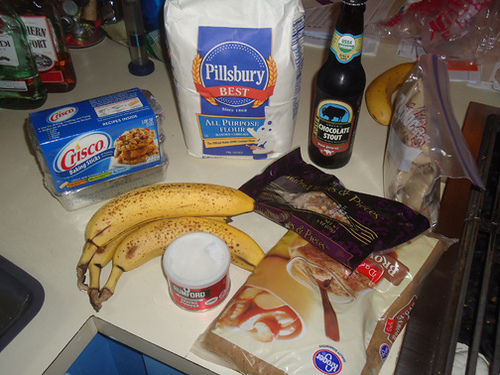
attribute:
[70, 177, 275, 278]
banana — yellow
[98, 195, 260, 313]
banana — yellow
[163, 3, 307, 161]
bag — blue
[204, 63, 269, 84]
text — white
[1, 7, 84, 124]
bottles — southern comfort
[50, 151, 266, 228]
banana — yellow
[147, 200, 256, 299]
lid — white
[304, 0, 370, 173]
beer — in bottle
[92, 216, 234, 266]
banana — yellow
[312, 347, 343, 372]
logo — blue, white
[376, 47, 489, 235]
bag — closed